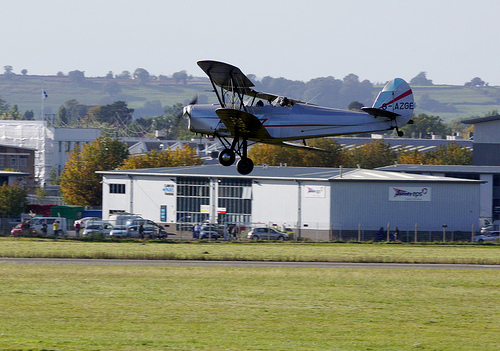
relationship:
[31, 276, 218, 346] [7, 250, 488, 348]
grass on field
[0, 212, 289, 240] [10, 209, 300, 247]
group of cars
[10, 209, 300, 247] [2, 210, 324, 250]
cars in lot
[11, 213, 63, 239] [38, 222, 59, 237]
van with people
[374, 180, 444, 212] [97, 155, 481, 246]
sign of building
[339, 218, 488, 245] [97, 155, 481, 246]
fence by building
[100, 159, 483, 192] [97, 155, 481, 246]
roof of building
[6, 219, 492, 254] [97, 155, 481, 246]
fence surrounds building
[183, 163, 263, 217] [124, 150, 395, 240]
windows on building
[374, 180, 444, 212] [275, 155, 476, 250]
sign on building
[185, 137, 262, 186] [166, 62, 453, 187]
landing gear on plane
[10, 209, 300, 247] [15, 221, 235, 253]
cars in parking lot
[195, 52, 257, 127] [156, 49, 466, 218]
wings on plane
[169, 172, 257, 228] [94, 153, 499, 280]
doors on building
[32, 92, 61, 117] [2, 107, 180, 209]
flagpole on building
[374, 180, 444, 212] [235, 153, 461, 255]
sign on building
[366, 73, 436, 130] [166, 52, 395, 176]
stablizer on plane